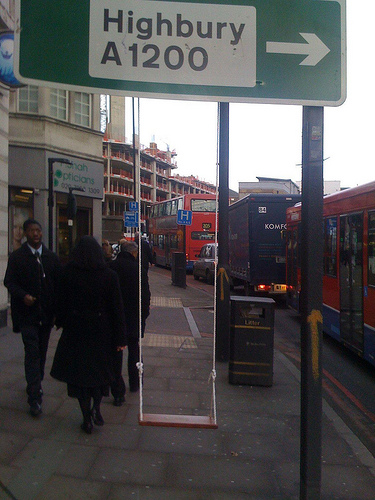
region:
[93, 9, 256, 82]
black letters on white sign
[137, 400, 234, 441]
a red swing seat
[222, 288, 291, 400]
a black and yellow trash can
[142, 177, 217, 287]
a red double decker bus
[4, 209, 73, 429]
a man in a suit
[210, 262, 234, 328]
a yellow arrow on pole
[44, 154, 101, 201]
green letters on the building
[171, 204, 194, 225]
a blue and white sign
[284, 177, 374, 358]
a regular red bus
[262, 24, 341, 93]
a white arrow on the sign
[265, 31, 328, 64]
a white arrow on the sign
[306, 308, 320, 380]
yellow paint on the post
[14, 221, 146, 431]
people walking on the sidewalk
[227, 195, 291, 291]
a blue box truck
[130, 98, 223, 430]
a swing hanging by the sidewalk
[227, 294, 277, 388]
a newspaper dispenser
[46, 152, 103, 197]
a business sign on the building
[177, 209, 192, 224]
a blue and white sign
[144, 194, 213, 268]
a red double decker bus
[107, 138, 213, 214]
a building under construction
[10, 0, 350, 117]
part of a green and white street sign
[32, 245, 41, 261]
part of a man's tie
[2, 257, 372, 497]
part of a sidewalk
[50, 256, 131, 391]
a woman's long black coat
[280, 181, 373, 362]
part of a red and blue bus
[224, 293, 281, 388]
a tall trashcan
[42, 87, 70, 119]
a window of a building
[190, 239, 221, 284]
part of a small car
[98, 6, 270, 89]
This is a sign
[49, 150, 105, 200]
This is a sign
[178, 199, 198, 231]
This is a sign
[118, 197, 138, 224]
This is a sign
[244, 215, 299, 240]
This is a sign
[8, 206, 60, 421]
this is a person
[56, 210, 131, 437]
this is a person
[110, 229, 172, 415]
this is a person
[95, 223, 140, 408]
this is a person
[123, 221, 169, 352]
this is a person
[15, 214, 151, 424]
people are walking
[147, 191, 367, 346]
the buses are on the road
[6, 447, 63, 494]
part of the gray ground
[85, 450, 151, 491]
part of the gray ground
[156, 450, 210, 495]
part of the gray ground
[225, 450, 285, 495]
part of the gray ground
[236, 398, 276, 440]
part of the gray ground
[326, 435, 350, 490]
part of the gray ground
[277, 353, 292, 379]
part of the gray ground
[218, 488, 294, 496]
part of the gray ground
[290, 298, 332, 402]
orange arrow painted pointed up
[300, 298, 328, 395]
orange arrow painted pointed up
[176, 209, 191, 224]
H on the street sign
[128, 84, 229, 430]
swing hanging from street sign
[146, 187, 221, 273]
bus is a double decker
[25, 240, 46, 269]
boy is wearing a tie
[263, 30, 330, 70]
white arrow on the street sign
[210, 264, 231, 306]
arrow painted on pole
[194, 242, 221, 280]
car behind the bus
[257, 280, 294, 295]
brake lights are on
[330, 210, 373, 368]
doors on the bus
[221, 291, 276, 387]
trash can next to pole